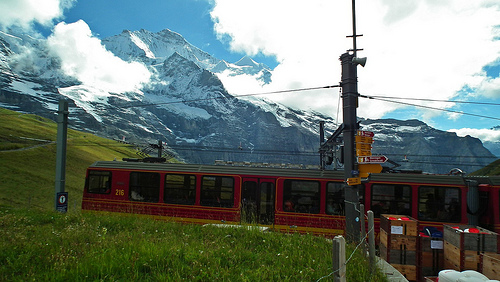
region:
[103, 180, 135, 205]
216 on the train.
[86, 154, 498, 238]
The train is mostly red.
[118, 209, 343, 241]
Yellow line on the train.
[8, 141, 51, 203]
The grass is green.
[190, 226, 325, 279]
Small flowers in the grass.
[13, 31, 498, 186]
Mountains in the background.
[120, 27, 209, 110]
Snow on the mountains.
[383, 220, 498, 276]
Boxes next to the train.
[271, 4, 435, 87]
Large cloud in the sky.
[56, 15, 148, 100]
Cloud in front of the mountain.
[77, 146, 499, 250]
train on the tracks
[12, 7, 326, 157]
snow covered mountains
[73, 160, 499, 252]
red and yellow train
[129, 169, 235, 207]
row of three windows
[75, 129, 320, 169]
ires running along side the train tracks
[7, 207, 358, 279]
field of greeng rass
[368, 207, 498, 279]
brown crates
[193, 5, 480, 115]
bright white cloud in the sky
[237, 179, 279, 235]
door of the train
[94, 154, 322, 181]
top of the train is gray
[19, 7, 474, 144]
Clouds in the sky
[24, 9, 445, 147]
All clouds are white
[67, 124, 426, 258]
Red and yellow train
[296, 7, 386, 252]
Pole in the ground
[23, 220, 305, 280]
Grass is high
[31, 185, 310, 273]
Dark green grass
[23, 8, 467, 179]
Mountains in the back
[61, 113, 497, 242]
Train is parked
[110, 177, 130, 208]
"216"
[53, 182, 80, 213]
A sign on the pole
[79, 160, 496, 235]
red train car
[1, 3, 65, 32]
white cloud in the blue sky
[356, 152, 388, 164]
long red narrow sign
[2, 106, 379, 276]
grassy, sloping hills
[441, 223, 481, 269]
brown wooden box on platform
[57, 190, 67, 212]
black sign with white circle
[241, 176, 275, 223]
doors on red train car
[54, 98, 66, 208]
tall green metal pole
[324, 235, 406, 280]
concrete curb near grass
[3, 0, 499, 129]
blue sky with clouds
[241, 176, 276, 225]
Red and black doors on train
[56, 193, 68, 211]
Sign attached to pole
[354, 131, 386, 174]
Group of signs attached to pole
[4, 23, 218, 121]
Large mountain range in background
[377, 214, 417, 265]
Group of wooden boxes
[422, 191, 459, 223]
Group of people inside train cart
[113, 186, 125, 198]
Yellow number 216 on side of train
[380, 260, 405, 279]
Small grey concrete wall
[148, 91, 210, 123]
Snow ontop of mountain range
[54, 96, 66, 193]
Large grey metal pole